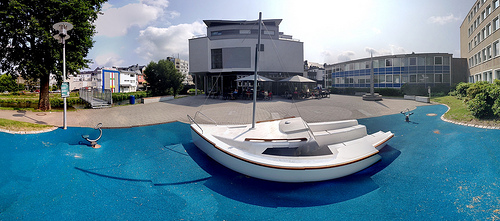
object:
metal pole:
[62, 35, 68, 129]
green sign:
[60, 82, 69, 97]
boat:
[189, 116, 395, 183]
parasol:
[277, 75, 317, 83]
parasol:
[234, 74, 275, 82]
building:
[188, 19, 304, 93]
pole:
[251, 12, 263, 128]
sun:
[284, 1, 366, 25]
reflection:
[73, 166, 214, 186]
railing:
[245, 137, 308, 141]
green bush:
[465, 87, 495, 117]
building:
[460, 0, 499, 88]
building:
[307, 66, 324, 90]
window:
[256, 43, 265, 51]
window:
[486, 22, 493, 35]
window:
[485, 45, 492, 58]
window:
[406, 57, 417, 67]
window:
[434, 55, 444, 65]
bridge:
[79, 86, 113, 109]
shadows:
[176, 97, 296, 103]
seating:
[232, 85, 323, 102]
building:
[324, 51, 468, 92]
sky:
[1, 2, 476, 83]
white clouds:
[105, 1, 197, 34]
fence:
[0, 99, 87, 111]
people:
[242, 82, 324, 101]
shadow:
[233, 185, 358, 202]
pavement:
[0, 96, 426, 118]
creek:
[2, 104, 474, 211]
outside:
[5, 6, 469, 204]